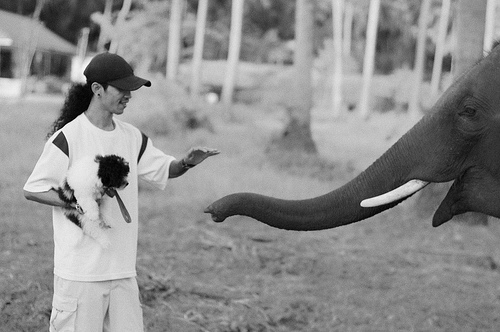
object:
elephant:
[204, 40, 499, 231]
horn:
[360, 178, 431, 207]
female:
[23, 53, 222, 331]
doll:
[59, 154, 131, 247]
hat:
[79, 50, 152, 91]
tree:
[220, 2, 244, 119]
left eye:
[463, 107, 478, 116]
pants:
[51, 276, 144, 331]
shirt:
[21, 109, 177, 284]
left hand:
[183, 146, 220, 167]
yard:
[4, 94, 500, 332]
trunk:
[204, 117, 433, 230]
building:
[1, 10, 80, 81]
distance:
[0, 1, 499, 90]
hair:
[45, 82, 93, 140]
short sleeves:
[19, 128, 68, 194]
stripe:
[50, 132, 69, 157]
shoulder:
[48, 127, 81, 160]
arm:
[137, 131, 173, 177]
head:
[426, 39, 499, 228]